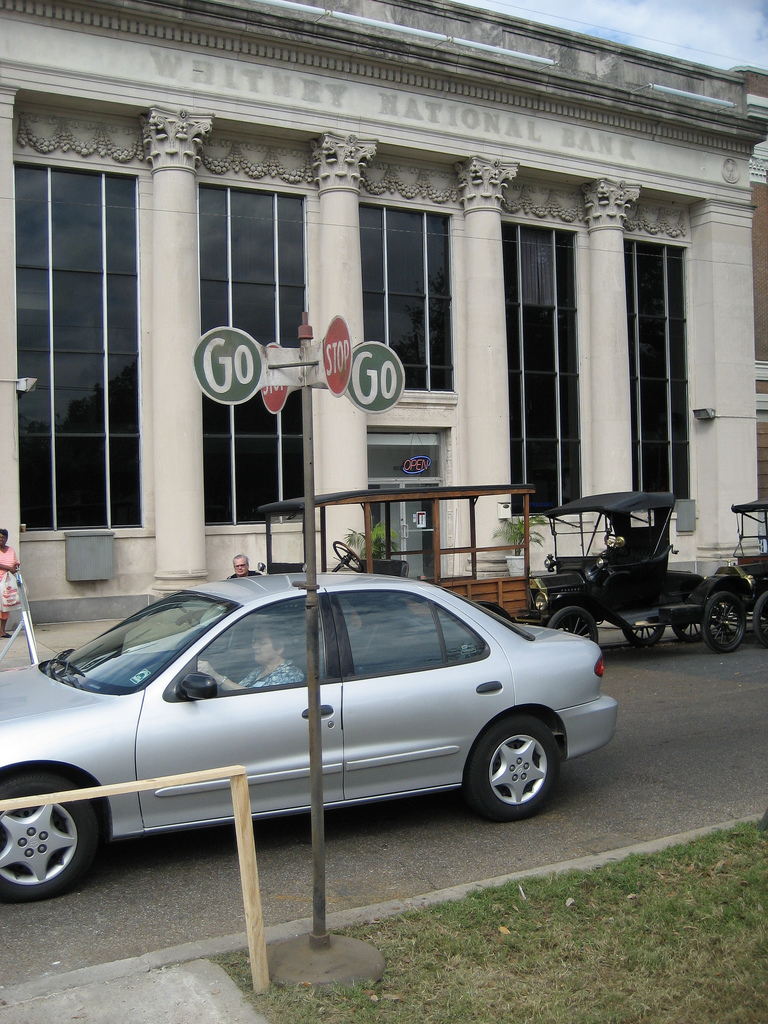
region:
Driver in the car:
[192, 612, 303, 705]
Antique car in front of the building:
[520, 442, 764, 653]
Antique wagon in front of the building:
[237, 467, 544, 666]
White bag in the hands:
[2, 559, 30, 619]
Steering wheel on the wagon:
[323, 529, 366, 573]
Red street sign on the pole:
[316, 316, 358, 397]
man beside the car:
[223, 549, 262, 587]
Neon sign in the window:
[400, 446, 435, 476]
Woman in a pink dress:
[0, 524, 26, 642]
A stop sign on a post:
[283, 307, 359, 401]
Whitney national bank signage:
[150, 46, 674, 177]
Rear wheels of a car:
[460, 711, 570, 829]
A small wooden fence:
[0, 735, 294, 991]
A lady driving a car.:
[176, 612, 326, 699]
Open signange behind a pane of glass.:
[393, 432, 442, 482]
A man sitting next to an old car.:
[217, 486, 543, 608]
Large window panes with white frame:
[493, 220, 611, 509]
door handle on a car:
[467, 668, 527, 704]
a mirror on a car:
[174, 655, 220, 718]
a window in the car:
[373, 593, 472, 671]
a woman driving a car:
[238, 613, 329, 701]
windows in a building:
[42, 263, 133, 383]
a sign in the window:
[392, 441, 458, 480]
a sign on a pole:
[290, 308, 374, 392]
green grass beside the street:
[517, 907, 658, 959]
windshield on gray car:
[42, 585, 239, 698]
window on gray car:
[167, 593, 337, 699]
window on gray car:
[333, 588, 450, 683]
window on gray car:
[433, 603, 486, 664]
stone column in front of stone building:
[144, 169, 211, 589]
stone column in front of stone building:
[323, 187, 372, 573]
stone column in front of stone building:
[463, 213, 510, 580]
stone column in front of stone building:
[589, 226, 632, 557]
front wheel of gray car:
[4, 771, 93, 902]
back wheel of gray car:
[465, 711, 558, 820]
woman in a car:
[194, 624, 304, 699]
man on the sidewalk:
[219, 552, 263, 587]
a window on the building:
[636, 213, 718, 503]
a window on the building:
[499, 223, 576, 458]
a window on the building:
[361, 141, 457, 376]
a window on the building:
[191, 135, 284, 487]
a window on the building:
[25, 116, 190, 554]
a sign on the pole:
[299, 306, 363, 408]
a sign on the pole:
[313, 332, 432, 461]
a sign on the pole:
[199, 325, 330, 419]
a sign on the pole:
[243, 310, 331, 409]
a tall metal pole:
[233, 726, 434, 1022]